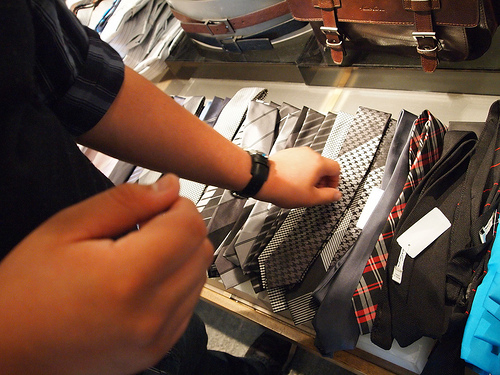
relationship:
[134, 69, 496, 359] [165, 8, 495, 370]
ties on table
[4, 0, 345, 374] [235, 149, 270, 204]
person wears watch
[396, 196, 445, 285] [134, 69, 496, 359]
tag on ties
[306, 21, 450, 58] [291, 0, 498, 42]
buckle on bag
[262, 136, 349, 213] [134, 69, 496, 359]
hand touches ties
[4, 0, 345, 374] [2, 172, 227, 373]
person has hand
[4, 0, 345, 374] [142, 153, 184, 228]
person has thumb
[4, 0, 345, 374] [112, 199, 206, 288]
person has finger